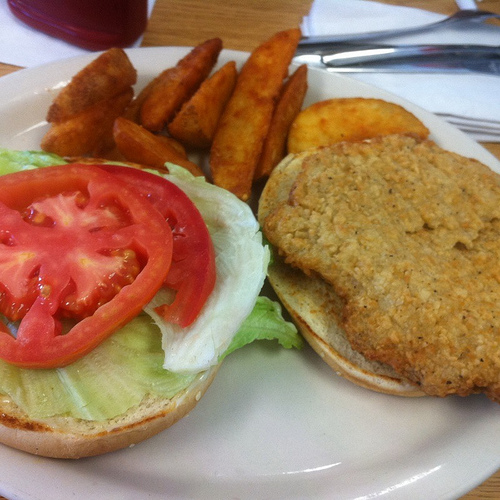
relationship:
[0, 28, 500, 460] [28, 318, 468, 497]
food on plate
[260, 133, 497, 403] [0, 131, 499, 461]
pork fritter on sandwich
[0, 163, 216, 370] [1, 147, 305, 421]
tomato on lettuce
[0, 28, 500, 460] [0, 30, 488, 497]
food on plate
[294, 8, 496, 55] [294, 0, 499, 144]
fork on napkin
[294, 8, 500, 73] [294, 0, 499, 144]
fork on napkin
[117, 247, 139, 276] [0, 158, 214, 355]
seeds are on tomatoes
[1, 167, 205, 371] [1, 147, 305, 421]
tomato on lettuce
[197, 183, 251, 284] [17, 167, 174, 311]
lettuce under tomato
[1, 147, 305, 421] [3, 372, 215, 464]
lettuce on bun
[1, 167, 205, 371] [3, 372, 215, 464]
tomato on bun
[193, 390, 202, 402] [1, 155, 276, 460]
sesame seed on bun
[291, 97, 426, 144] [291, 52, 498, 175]
potato on plate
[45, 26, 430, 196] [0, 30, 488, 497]
potato wedges on plate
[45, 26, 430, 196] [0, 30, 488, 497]
potato wedges are on plate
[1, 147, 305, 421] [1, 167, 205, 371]
lettuce under tomato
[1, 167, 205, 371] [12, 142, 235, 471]
tomato under bun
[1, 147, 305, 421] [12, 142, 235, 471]
lettuce under bun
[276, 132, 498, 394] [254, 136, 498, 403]
chicken patty on bun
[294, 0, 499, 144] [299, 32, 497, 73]
napkin under utensils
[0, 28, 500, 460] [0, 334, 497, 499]
food on plate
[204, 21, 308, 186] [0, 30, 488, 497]
food on plate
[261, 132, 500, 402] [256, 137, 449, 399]
chicken patty on bread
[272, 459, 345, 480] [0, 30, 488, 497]
reflection on plate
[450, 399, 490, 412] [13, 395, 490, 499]
shadow on plate